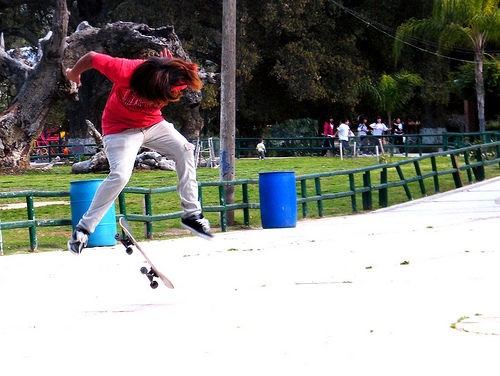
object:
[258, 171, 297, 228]
barrel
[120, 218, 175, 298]
skateboard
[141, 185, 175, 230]
air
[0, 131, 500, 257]
fence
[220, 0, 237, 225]
pole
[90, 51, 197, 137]
t-shirt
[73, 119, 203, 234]
pants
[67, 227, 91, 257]
shoes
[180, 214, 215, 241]
shoes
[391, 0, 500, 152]
tree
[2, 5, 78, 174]
tree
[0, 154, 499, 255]
grass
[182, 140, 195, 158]
knee patch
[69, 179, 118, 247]
trash can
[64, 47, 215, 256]
skateboarder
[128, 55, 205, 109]
hair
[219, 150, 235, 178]
paint spot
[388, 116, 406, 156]
people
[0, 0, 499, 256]
park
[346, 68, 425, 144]
weeping tree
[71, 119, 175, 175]
branch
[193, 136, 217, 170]
ladder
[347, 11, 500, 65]
telephone wires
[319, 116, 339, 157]
woman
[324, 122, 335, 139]
shirt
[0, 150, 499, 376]
ground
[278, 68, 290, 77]
leaves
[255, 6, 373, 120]
tree